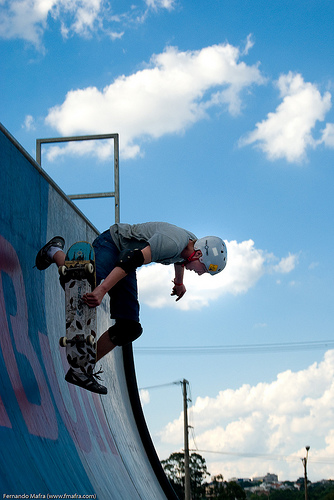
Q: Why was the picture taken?
A: To capture the man skate boarding.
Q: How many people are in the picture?
A: One.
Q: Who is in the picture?
A: A man.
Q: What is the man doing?
A: Skateboarding.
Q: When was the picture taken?
A: During the day.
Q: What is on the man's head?
A: A helmet.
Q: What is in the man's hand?
A: A skateboard.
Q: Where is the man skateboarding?
A: On a ramp.